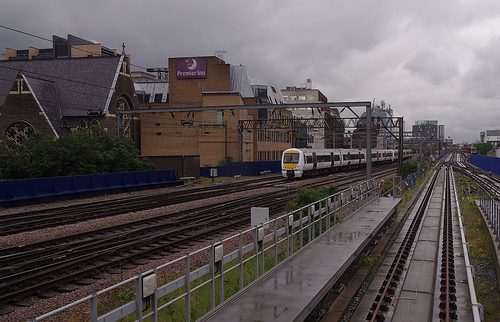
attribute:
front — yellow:
[278, 148, 308, 180]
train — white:
[275, 143, 416, 183]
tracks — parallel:
[3, 152, 398, 321]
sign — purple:
[173, 56, 210, 81]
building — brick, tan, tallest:
[137, 56, 309, 179]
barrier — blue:
[3, 166, 180, 204]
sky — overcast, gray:
[3, 2, 499, 130]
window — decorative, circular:
[3, 120, 39, 161]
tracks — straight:
[361, 150, 495, 316]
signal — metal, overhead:
[114, 107, 406, 183]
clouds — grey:
[298, 7, 490, 102]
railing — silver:
[49, 174, 383, 321]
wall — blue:
[3, 158, 282, 206]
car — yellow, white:
[279, 145, 342, 180]